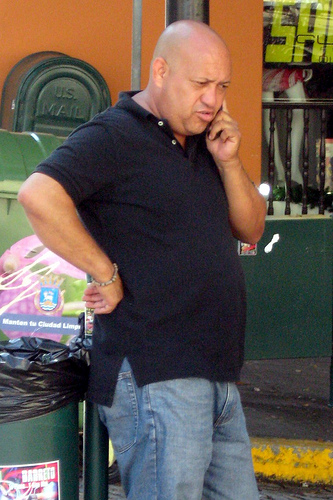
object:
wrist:
[92, 263, 117, 284]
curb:
[248, 437, 330, 485]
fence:
[263, 98, 333, 216]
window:
[260, 1, 331, 201]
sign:
[0, 460, 59, 500]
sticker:
[1, 458, 85, 499]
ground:
[245, 120, 255, 141]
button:
[158, 121, 164, 126]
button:
[172, 139, 177, 145]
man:
[18, 20, 268, 499]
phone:
[208, 103, 223, 141]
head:
[148, 17, 231, 136]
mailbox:
[0, 49, 112, 137]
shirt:
[31, 90, 247, 409]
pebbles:
[254, 386, 261, 392]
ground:
[239, 358, 330, 498]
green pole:
[82, 404, 108, 500]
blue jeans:
[97, 358, 260, 500]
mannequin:
[260, 60, 312, 185]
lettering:
[264, 0, 333, 64]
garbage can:
[0, 335, 88, 500]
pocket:
[97, 371, 138, 456]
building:
[0, 1, 330, 398]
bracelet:
[91, 263, 118, 287]